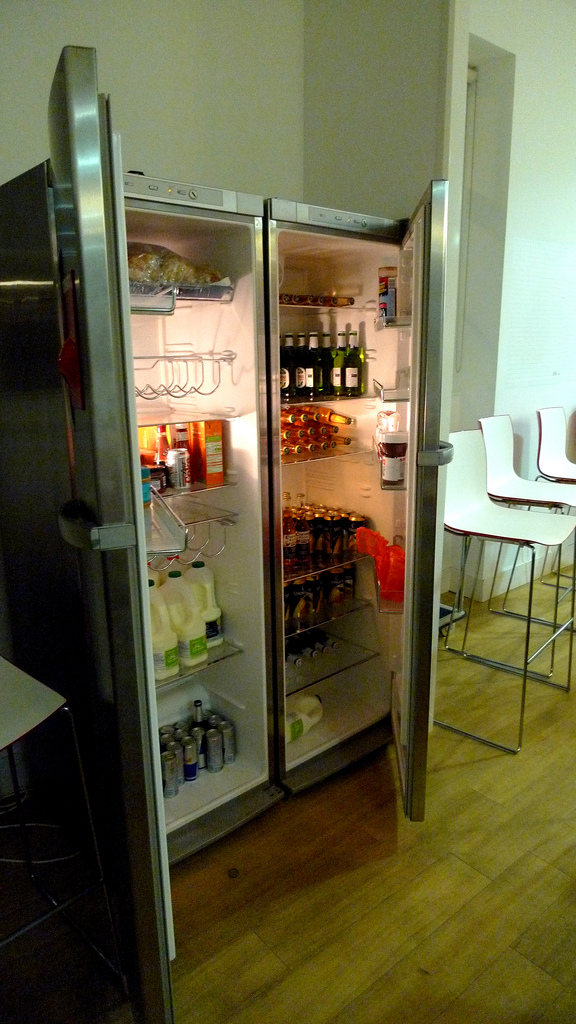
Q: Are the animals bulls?
A: Yes, all the animals are bulls.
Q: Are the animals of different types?
A: No, all the animals are bulls.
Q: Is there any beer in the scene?
A: Yes, there is beer.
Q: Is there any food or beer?
A: Yes, there is beer.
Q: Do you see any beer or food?
A: Yes, there is beer.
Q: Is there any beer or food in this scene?
A: Yes, there is beer.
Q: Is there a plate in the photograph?
A: No, there are no plates.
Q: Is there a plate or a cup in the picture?
A: No, there are no plates or cups.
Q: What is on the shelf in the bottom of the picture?
A: The beer is on the shelf.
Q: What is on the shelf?
A: The beer is on the shelf.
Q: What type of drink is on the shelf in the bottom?
A: The drink is beer.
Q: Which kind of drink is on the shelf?
A: The drink is beer.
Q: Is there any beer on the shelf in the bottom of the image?
A: Yes, there is beer on the shelf.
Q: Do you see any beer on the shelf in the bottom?
A: Yes, there is beer on the shelf.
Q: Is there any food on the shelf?
A: No, there is beer on the shelf.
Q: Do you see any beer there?
A: Yes, there is beer.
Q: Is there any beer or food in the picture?
A: Yes, there is beer.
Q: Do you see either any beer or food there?
A: Yes, there is beer.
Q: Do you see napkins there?
A: No, there are no napkins.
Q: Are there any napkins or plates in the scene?
A: No, there are no napkins or plates.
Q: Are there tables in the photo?
A: No, there are no tables.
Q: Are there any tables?
A: No, there are no tables.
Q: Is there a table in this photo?
A: No, there are no tables.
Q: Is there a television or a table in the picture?
A: No, there are no tables or televisions.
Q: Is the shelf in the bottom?
A: Yes, the shelf is in the bottom of the image.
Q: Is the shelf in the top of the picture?
A: No, the shelf is in the bottom of the image.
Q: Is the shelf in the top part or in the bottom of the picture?
A: The shelf is in the bottom of the image.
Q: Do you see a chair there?
A: Yes, there is a chair.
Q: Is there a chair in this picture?
A: Yes, there is a chair.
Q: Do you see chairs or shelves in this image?
A: Yes, there is a chair.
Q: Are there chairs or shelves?
A: Yes, there is a chair.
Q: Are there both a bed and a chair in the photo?
A: No, there is a chair but no beds.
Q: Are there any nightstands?
A: No, there are no nightstands.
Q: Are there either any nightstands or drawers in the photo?
A: No, there are no nightstands or drawers.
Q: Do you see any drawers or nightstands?
A: No, there are no nightstands or drawers.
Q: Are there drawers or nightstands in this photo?
A: No, there are no nightstands or drawers.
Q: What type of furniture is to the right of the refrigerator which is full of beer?
A: The piece of furniture is a chair.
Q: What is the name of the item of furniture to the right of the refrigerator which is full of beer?
A: The piece of furniture is a chair.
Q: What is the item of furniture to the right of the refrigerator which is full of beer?
A: The piece of furniture is a chair.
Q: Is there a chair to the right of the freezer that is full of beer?
A: Yes, there is a chair to the right of the freezer.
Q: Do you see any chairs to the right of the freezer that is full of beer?
A: Yes, there is a chair to the right of the freezer.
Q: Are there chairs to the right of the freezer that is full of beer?
A: Yes, there is a chair to the right of the freezer.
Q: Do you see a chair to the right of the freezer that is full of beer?
A: Yes, there is a chair to the right of the freezer.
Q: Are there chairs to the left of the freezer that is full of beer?
A: No, the chair is to the right of the freezer.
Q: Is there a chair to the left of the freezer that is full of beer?
A: No, the chair is to the right of the freezer.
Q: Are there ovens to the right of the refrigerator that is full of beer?
A: No, there is a chair to the right of the refrigerator.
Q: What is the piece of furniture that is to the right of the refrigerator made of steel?
A: The piece of furniture is a chair.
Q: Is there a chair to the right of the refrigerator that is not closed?
A: Yes, there is a chair to the right of the fridge.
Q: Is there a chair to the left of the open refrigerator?
A: No, the chair is to the right of the fridge.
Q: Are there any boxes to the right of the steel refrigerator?
A: No, there is a chair to the right of the refrigerator.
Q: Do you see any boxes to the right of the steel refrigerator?
A: No, there is a chair to the right of the refrigerator.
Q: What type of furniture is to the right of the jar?
A: The piece of furniture is a chair.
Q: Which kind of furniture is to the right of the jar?
A: The piece of furniture is a chair.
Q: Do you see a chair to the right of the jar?
A: Yes, there is a chair to the right of the jar.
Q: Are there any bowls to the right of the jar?
A: No, there is a chair to the right of the jar.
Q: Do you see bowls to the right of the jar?
A: No, there is a chair to the right of the jar.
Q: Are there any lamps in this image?
A: No, there are no lamps.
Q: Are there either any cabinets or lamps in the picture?
A: No, there are no lamps or cabinets.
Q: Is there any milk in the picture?
A: Yes, there is milk.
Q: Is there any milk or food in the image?
A: Yes, there is milk.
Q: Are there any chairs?
A: Yes, there is a chair.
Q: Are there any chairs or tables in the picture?
A: Yes, there is a chair.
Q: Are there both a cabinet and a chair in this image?
A: No, there is a chair but no cabinets.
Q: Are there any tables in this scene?
A: No, there are no tables.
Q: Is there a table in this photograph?
A: No, there are no tables.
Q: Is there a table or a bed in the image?
A: No, there are no tables or beds.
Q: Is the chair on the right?
A: Yes, the chair is on the right of the image.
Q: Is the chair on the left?
A: No, the chair is on the right of the image.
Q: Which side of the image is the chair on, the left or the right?
A: The chair is on the right of the image.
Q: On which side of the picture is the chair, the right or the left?
A: The chair is on the right of the image.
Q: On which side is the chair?
A: The chair is on the right of the image.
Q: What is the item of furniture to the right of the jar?
A: The piece of furniture is a chair.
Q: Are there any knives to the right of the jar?
A: No, there is a chair to the right of the jar.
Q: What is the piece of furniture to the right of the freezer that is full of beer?
A: The piece of furniture is a chair.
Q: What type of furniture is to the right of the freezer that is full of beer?
A: The piece of furniture is a chair.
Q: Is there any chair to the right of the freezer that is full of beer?
A: Yes, there is a chair to the right of the refrigerator.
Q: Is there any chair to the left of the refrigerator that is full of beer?
A: No, the chair is to the right of the refrigerator.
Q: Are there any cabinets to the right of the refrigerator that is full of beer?
A: No, there is a chair to the right of the freezer.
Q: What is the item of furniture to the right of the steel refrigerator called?
A: The piece of furniture is a chair.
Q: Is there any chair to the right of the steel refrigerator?
A: Yes, there is a chair to the right of the freezer.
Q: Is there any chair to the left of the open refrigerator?
A: No, the chair is to the right of the refrigerator.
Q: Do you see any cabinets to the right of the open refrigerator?
A: No, there is a chair to the right of the refrigerator.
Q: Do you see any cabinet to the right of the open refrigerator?
A: No, there is a chair to the right of the refrigerator.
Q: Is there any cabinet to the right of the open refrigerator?
A: No, there is a chair to the right of the refrigerator.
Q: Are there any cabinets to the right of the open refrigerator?
A: No, there is a chair to the right of the refrigerator.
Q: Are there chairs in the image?
A: Yes, there is a chair.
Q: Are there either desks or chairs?
A: Yes, there is a chair.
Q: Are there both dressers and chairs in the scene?
A: No, there is a chair but no dressers.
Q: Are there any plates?
A: No, there are no plates.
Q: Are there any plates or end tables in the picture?
A: No, there are no plates or end tables.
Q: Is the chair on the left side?
A: No, the chair is on the right of the image.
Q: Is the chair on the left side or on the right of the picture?
A: The chair is on the right of the image.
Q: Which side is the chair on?
A: The chair is on the right of the image.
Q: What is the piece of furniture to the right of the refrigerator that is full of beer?
A: The piece of furniture is a chair.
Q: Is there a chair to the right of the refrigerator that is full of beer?
A: Yes, there is a chair to the right of the refrigerator.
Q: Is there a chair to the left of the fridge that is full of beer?
A: No, the chair is to the right of the fridge.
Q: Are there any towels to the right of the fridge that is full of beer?
A: No, there is a chair to the right of the fridge.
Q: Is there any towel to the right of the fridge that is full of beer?
A: No, there is a chair to the right of the fridge.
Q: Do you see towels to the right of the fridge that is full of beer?
A: No, there is a chair to the right of the fridge.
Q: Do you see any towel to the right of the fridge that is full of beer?
A: No, there is a chair to the right of the fridge.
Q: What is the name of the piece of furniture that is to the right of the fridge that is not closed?
A: The piece of furniture is a chair.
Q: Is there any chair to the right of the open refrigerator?
A: Yes, there is a chair to the right of the refrigerator.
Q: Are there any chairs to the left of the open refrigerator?
A: No, the chair is to the right of the freezer.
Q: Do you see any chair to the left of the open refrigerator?
A: No, the chair is to the right of the freezer.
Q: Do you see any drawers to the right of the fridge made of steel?
A: No, there is a chair to the right of the fridge.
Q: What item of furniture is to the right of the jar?
A: The piece of furniture is a chair.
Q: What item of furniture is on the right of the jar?
A: The piece of furniture is a chair.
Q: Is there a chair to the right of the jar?
A: Yes, there is a chair to the right of the jar.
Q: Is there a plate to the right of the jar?
A: No, there is a chair to the right of the jar.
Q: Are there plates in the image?
A: No, there are no plates.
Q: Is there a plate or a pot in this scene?
A: No, there are no plates or pots.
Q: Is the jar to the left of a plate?
A: No, the jar is to the left of the chair.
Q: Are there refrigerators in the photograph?
A: Yes, there is a refrigerator.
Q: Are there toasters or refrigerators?
A: Yes, there is a refrigerator.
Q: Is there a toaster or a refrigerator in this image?
A: Yes, there is a refrigerator.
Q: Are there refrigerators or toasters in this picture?
A: Yes, there is a refrigerator.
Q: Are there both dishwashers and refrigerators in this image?
A: No, there is a refrigerator but no dishwashers.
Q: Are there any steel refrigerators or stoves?
A: Yes, there is a steel refrigerator.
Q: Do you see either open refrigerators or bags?
A: Yes, there is an open refrigerator.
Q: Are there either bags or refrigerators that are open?
A: Yes, the refrigerator is open.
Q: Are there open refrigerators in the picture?
A: Yes, there is an open refrigerator.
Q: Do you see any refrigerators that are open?
A: Yes, there is a refrigerator that is open.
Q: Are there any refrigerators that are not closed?
A: Yes, there is a open refrigerator.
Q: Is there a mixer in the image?
A: No, there are no mixers.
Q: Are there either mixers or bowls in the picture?
A: No, there are no mixers or bowls.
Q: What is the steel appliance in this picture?
A: The appliance is a refrigerator.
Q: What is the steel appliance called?
A: The appliance is a refrigerator.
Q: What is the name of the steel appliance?
A: The appliance is a refrigerator.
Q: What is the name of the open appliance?
A: The appliance is a refrigerator.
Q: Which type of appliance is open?
A: The appliance is a refrigerator.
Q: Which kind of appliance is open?
A: The appliance is a refrigerator.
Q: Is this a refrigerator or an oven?
A: This is a refrigerator.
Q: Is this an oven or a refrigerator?
A: This is a refrigerator.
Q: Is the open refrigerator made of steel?
A: Yes, the fridge is made of steel.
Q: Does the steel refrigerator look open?
A: Yes, the freezer is open.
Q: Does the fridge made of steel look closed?
A: No, the refrigerator is open.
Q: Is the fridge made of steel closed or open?
A: The freezer is open.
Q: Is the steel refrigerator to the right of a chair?
A: No, the fridge is to the left of a chair.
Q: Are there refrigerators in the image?
A: Yes, there is a refrigerator.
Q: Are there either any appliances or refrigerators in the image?
A: Yes, there is a refrigerator.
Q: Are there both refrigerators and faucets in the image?
A: No, there is a refrigerator but no faucets.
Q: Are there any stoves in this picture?
A: No, there are no stoves.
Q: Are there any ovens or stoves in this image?
A: No, there are no stoves or ovens.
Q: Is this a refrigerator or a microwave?
A: This is a refrigerator.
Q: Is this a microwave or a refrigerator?
A: This is a refrigerator.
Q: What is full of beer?
A: The freezer is full of beer.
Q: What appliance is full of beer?
A: The appliance is a refrigerator.